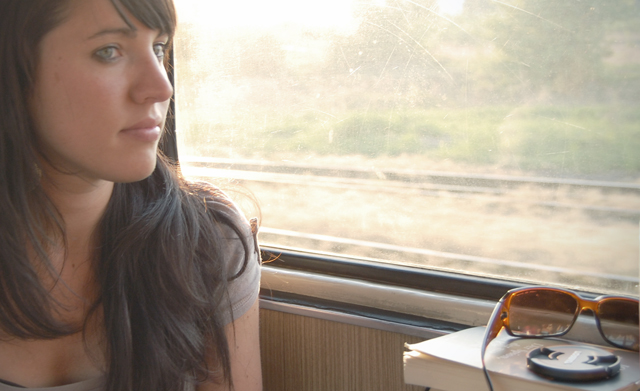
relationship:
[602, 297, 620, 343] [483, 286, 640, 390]
lens on glasses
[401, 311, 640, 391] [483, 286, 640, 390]
book under glasses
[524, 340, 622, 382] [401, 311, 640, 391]
coffee mug-lid on book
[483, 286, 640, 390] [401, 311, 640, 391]
glasses on book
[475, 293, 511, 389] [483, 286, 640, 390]
arm on glasses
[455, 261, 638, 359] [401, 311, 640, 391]
glasses on top of a book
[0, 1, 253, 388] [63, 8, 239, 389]
lady has hair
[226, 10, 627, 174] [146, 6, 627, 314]
trees outside window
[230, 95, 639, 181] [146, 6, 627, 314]
bushes outside window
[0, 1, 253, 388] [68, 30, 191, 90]
lady has eyes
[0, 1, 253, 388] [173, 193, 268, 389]
lady has arm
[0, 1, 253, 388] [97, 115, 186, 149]
lady has lips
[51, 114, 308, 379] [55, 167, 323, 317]
hair across shoulder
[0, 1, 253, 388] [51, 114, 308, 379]
lady has hair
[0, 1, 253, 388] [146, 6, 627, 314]
lady sitting by window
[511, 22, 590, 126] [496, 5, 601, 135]
leaves are on tree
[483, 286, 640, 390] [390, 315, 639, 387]
glasses are on book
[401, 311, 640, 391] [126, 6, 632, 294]
book beside window